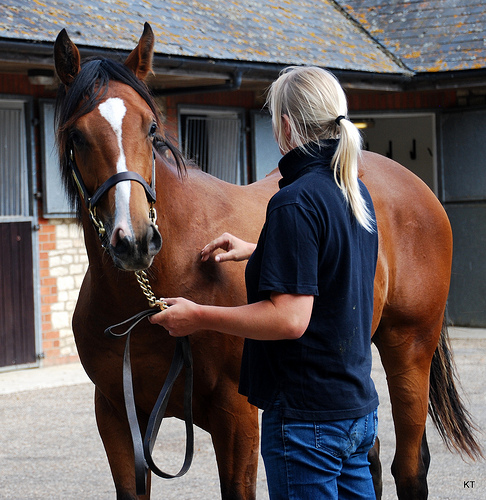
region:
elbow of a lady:
[265, 279, 321, 351]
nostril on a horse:
[140, 219, 171, 260]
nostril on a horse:
[90, 221, 134, 272]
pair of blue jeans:
[247, 373, 406, 497]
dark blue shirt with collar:
[220, 133, 397, 423]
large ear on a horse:
[115, 10, 170, 83]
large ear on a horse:
[47, 24, 83, 88]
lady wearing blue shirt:
[140, 60, 405, 499]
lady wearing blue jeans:
[129, 60, 405, 499]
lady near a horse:
[147, 50, 402, 499]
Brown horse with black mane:
[31, 22, 229, 276]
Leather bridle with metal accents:
[33, 18, 207, 298]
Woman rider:
[226, 68, 423, 388]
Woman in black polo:
[235, 45, 428, 419]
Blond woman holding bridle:
[237, 40, 443, 414]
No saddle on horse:
[195, 109, 334, 294]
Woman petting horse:
[154, 74, 383, 484]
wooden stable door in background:
[0, 112, 54, 363]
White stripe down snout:
[31, 24, 175, 294]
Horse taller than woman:
[57, 21, 391, 465]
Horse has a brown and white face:
[32, 10, 206, 287]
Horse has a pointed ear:
[126, 15, 164, 86]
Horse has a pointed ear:
[30, 14, 94, 82]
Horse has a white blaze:
[96, 92, 139, 248]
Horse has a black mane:
[76, 45, 166, 122]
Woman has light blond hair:
[255, 53, 396, 241]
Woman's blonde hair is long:
[255, 49, 389, 246]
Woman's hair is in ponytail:
[256, 41, 402, 240]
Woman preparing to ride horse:
[156, 49, 430, 494]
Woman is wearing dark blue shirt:
[228, 128, 419, 417]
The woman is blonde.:
[259, 60, 385, 235]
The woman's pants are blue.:
[258, 395, 383, 498]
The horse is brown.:
[43, 27, 467, 497]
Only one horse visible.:
[41, 22, 463, 498]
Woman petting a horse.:
[143, 60, 395, 495]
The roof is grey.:
[1, 1, 483, 85]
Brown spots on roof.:
[1, 2, 482, 75]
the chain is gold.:
[130, 263, 171, 308]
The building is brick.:
[24, 177, 91, 369]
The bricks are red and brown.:
[35, 207, 98, 368]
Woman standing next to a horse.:
[249, 65, 414, 492]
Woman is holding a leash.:
[101, 282, 203, 488]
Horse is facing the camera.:
[46, 40, 192, 282]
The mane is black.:
[49, 48, 166, 102]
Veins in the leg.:
[374, 332, 433, 439]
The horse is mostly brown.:
[55, 29, 249, 492]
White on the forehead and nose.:
[89, 90, 143, 254]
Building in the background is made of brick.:
[32, 233, 82, 352]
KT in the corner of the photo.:
[452, 470, 484, 499]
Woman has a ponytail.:
[328, 102, 371, 240]